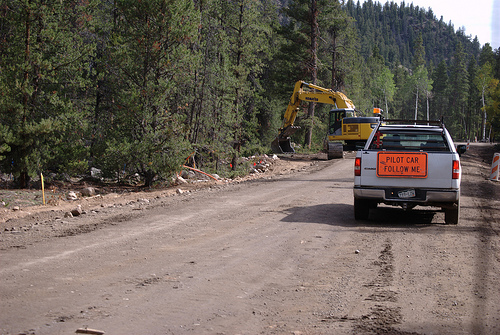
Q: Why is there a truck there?
A: It's a construction site.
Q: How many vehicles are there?
A: Two.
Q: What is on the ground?
A: Dirt.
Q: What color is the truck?
A: White.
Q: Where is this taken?
A: On a dirt road.